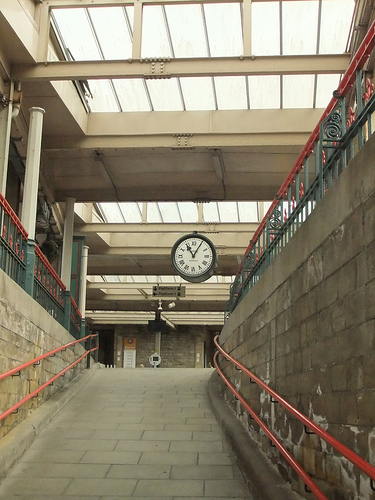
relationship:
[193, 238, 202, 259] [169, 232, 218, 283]
arrows are on a clock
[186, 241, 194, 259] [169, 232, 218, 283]
arrows are on a clock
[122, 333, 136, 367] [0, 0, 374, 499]
sign for station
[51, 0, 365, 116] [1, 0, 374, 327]
windows in ceiling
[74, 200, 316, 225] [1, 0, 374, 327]
windows in ceiling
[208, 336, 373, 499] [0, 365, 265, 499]
rails are near ramp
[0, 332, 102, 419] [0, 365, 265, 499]
rails are near ramp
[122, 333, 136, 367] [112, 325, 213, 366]
sign on wall wall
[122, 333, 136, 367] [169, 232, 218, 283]
sign behind clock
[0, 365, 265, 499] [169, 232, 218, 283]
ramp below clock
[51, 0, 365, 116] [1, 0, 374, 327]
windows are in ceiling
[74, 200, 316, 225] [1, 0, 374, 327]
windows are in ceiling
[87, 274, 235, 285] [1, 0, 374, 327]
windows are in ceiling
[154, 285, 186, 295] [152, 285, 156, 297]
sign shows directions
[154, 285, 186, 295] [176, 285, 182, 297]
sign shows directions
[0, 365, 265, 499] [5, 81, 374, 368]
ramp going to main level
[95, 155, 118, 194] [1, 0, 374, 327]
light on ceiling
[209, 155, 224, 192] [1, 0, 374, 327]
light on ceiling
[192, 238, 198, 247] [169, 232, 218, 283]
number on clock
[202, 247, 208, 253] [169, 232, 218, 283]
number on clock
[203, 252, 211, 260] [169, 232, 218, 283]
number on clock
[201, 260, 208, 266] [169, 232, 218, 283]
number on clock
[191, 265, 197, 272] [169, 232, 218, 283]
number on clock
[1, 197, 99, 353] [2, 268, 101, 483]
fence near wall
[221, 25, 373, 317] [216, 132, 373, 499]
fence near wall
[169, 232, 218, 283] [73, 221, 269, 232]
clock on beams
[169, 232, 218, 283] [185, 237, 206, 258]
clock showing time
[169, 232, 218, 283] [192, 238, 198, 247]
clock has number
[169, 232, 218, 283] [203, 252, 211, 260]
clock has number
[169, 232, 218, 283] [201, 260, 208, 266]
clock has number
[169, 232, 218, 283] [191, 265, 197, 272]
clock has number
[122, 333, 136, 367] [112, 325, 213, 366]
sign on wall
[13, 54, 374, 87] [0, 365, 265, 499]
beams are above ramp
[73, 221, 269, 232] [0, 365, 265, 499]
beams are above ramp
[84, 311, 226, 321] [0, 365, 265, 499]
beams are above ramp